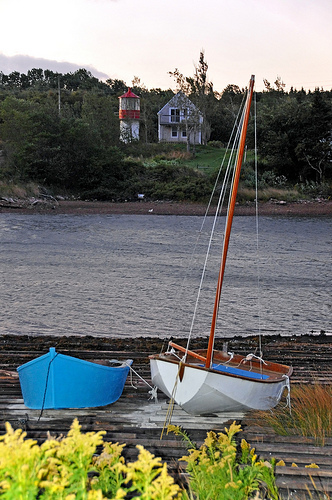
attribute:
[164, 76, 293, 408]
boat — blue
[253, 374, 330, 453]
weeds — growing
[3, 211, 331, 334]
water — low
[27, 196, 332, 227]
shoreline — rocky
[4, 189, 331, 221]
shore — part of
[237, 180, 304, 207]
grass — part of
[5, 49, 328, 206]
forest — part of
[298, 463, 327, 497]
flower — part of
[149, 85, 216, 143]
building — part of